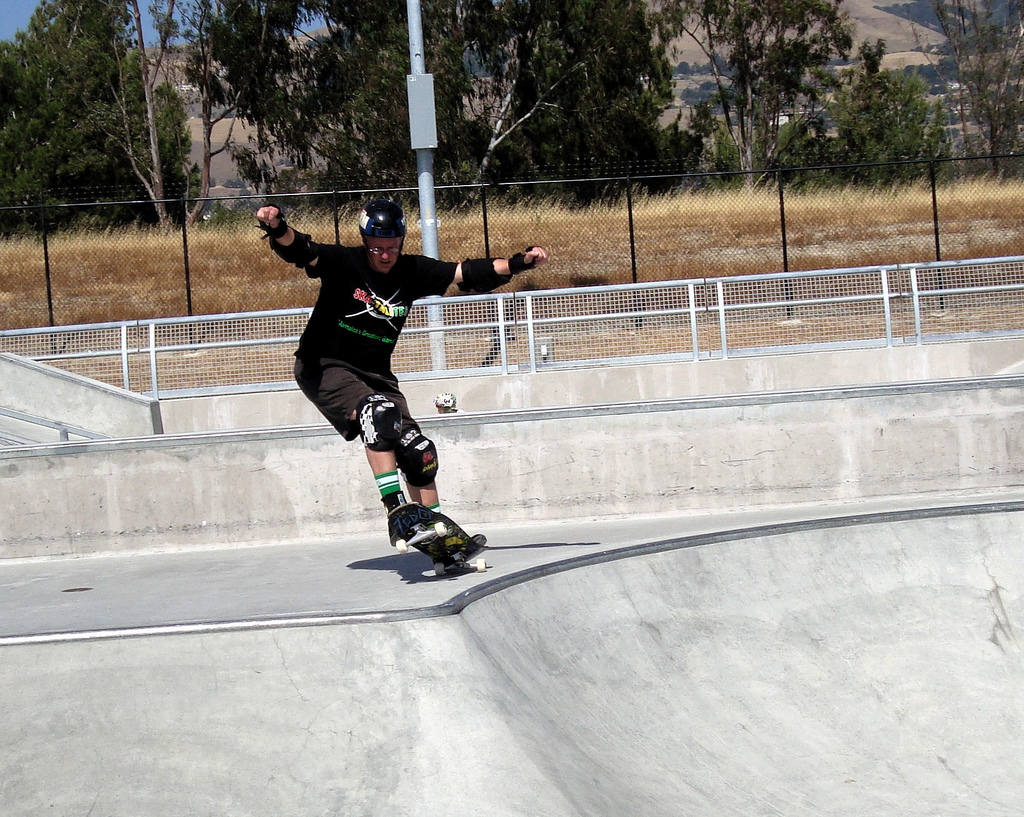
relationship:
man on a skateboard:
[250, 197, 549, 527] [383, 490, 494, 576]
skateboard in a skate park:
[377, 497, 491, 574] [26, 193, 1005, 812]